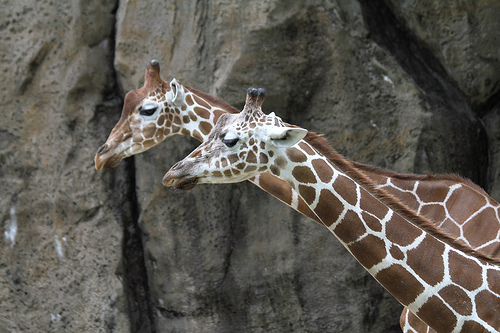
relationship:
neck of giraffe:
[295, 136, 494, 333] [154, 111, 496, 333]